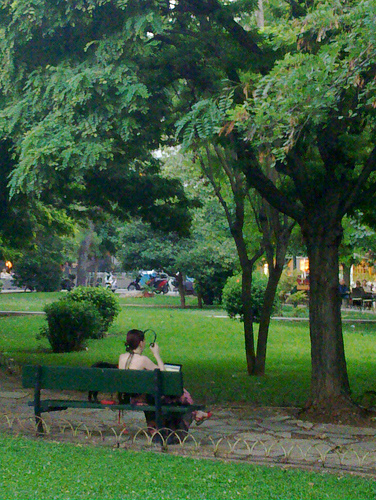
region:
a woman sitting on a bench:
[32, 301, 268, 475]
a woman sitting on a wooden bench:
[5, 286, 247, 498]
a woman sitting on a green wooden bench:
[17, 291, 252, 443]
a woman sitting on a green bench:
[27, 291, 240, 463]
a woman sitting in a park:
[11, 303, 344, 497]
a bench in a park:
[7, 290, 332, 497]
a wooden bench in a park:
[8, 282, 327, 489]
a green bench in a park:
[17, 274, 301, 497]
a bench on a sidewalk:
[0, 281, 259, 492]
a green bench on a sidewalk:
[23, 306, 257, 467]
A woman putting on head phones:
[115, 323, 167, 380]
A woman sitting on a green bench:
[114, 326, 167, 436]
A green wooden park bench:
[13, 353, 214, 447]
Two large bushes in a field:
[40, 280, 123, 354]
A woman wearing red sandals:
[177, 392, 222, 434]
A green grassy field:
[173, 321, 228, 358]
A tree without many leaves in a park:
[220, 222, 290, 392]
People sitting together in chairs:
[348, 273, 375, 315]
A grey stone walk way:
[231, 411, 303, 451]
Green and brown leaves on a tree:
[182, 83, 302, 165]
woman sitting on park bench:
[26, 328, 197, 430]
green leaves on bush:
[224, 273, 280, 318]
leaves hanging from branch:
[0, 23, 157, 190]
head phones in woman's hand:
[138, 329, 160, 352]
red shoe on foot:
[192, 407, 215, 426]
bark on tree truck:
[311, 312, 345, 415]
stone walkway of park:
[0, 397, 374, 451]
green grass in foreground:
[1, 434, 373, 497]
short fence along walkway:
[6, 415, 363, 466]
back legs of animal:
[85, 388, 102, 405]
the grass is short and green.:
[176, 320, 217, 352]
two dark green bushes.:
[25, 279, 119, 348]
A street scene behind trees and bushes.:
[2, 254, 373, 308]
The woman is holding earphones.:
[125, 327, 157, 356]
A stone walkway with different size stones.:
[1, 381, 375, 476]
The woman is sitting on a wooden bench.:
[22, 327, 212, 433]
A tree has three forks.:
[237, 249, 286, 376]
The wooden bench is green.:
[19, 364, 203, 443]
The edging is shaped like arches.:
[2, 414, 373, 469]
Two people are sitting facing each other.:
[349, 277, 373, 310]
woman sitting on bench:
[115, 319, 173, 402]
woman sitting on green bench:
[114, 326, 163, 407]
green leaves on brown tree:
[12, 53, 72, 126]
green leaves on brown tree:
[5, 117, 56, 195]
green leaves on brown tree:
[13, 194, 69, 263]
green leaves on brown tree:
[70, 169, 132, 240]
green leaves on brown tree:
[146, 179, 208, 250]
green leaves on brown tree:
[92, 63, 145, 124]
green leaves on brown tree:
[186, 112, 241, 156]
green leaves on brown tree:
[274, 50, 343, 133]